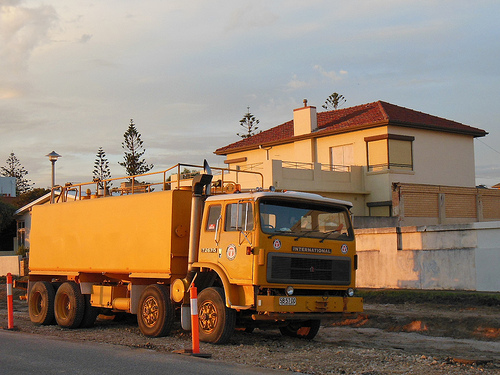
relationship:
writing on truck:
[286, 246, 335, 254] [13, 176, 371, 348]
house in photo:
[215, 97, 490, 226] [5, 2, 497, 370]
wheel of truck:
[29, 282, 54, 328] [13, 176, 371, 348]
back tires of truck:
[53, 281, 90, 326] [13, 176, 371, 348]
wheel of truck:
[194, 285, 230, 345] [13, 176, 371, 348]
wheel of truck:
[281, 322, 325, 342] [13, 176, 371, 348]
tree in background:
[4, 152, 35, 204] [2, 56, 500, 208]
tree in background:
[89, 145, 115, 196] [2, 56, 500, 208]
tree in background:
[116, 121, 157, 191] [2, 56, 500, 208]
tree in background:
[240, 108, 269, 137] [2, 56, 500, 208]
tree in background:
[320, 97, 353, 110] [2, 56, 500, 208]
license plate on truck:
[275, 295, 302, 305] [13, 176, 371, 348]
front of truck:
[196, 185, 368, 343] [13, 176, 371, 348]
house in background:
[215, 97, 490, 226] [2, 56, 500, 208]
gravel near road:
[18, 309, 464, 372] [0, 327, 216, 364]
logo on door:
[226, 244, 242, 262] [199, 201, 258, 288]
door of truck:
[199, 201, 258, 288] [13, 176, 371, 348]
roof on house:
[214, 96, 491, 158] [215, 97, 490, 226]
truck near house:
[13, 176, 371, 348] [215, 97, 490, 226]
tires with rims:
[26, 275, 241, 348] [31, 290, 220, 330]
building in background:
[215, 97, 490, 226] [2, 56, 500, 208]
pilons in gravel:
[0, 275, 211, 353] [18, 309, 464, 372]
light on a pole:
[47, 151, 64, 165] [47, 162, 59, 204]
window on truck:
[255, 203, 355, 236] [13, 176, 371, 348]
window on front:
[255, 203, 355, 236] [196, 185, 368, 343]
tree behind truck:
[89, 145, 115, 196] [13, 176, 371, 348]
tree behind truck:
[116, 121, 157, 191] [13, 176, 371, 348]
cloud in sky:
[26, 5, 458, 180] [8, 6, 498, 190]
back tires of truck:
[27, 280, 99, 327] [13, 176, 371, 348]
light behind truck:
[43, 148, 63, 164] [13, 176, 371, 348]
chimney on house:
[290, 97, 320, 139] [215, 97, 490, 226]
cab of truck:
[196, 185, 368, 343] [13, 176, 371, 348]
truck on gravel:
[13, 176, 371, 348] [18, 309, 464, 372]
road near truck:
[0, 327, 216, 364] [13, 176, 371, 348]